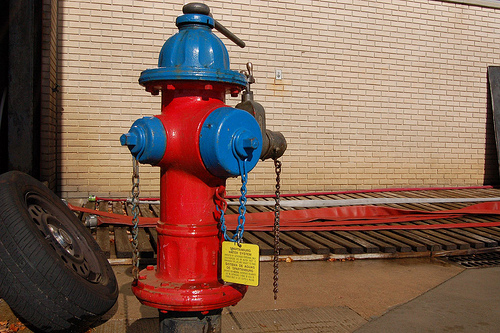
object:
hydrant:
[119, 2, 288, 333]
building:
[0, 0, 499, 195]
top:
[137, 3, 255, 84]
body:
[122, 81, 264, 314]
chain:
[218, 176, 248, 245]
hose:
[67, 202, 497, 231]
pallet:
[80, 185, 499, 260]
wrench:
[182, 1, 246, 49]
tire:
[0, 168, 121, 333]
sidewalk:
[89, 262, 497, 330]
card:
[221, 241, 260, 287]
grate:
[450, 250, 499, 269]